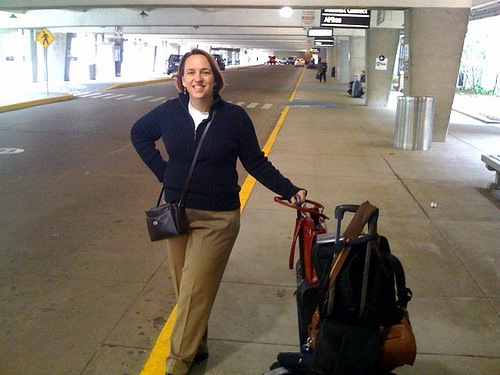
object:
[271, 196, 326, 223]
handle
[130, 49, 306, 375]
she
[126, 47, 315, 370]
woman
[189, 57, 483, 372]
sidewalk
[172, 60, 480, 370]
roadside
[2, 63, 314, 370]
road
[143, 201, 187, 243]
purse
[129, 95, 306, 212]
sweater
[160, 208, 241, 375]
beige pants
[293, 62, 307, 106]
yellow stripe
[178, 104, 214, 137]
white shirt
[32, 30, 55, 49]
yellow sign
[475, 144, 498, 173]
wooden bench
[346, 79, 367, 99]
blue suitcase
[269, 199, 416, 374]
black suitcase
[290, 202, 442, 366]
pile of luggage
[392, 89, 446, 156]
trash can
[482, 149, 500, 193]
bench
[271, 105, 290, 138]
yellow curb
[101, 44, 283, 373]
woman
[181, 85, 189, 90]
earring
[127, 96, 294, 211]
blue shirt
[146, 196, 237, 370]
tan pants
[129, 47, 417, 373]
holding luggage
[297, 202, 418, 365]
suitcase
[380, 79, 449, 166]
trash can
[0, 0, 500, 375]
airport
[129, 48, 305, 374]
she is standing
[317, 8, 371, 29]
sign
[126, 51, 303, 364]
woman standing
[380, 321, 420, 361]
bag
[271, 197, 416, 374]
luggage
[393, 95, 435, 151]
dustbin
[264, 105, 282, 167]
yellow paint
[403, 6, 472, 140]
poles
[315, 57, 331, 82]
man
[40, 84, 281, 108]
crossing mark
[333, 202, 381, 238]
luggage handle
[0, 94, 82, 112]
sidewalk line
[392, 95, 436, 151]
silver container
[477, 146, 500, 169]
bench portion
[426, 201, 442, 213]
paper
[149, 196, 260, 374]
woman's slacks